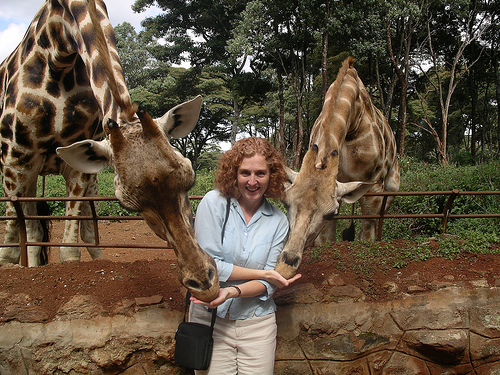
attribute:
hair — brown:
[212, 137, 289, 203]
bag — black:
[172, 286, 219, 373]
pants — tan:
[186, 299, 278, 374]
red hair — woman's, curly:
[218, 137, 285, 199]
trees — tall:
[105, 7, 205, 189]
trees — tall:
[189, 2, 282, 175]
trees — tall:
[290, 7, 382, 186]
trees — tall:
[377, 2, 451, 189]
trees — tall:
[423, 2, 495, 172]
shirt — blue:
[187, 187, 297, 298]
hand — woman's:
[263, 250, 303, 290]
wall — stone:
[0, 292, 491, 372]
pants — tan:
[178, 297, 278, 373]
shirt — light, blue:
[189, 196, 321, 309]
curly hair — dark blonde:
[221, 138, 288, 199]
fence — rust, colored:
[1, 188, 498, 265]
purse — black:
[164, 282, 211, 369]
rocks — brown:
[335, 299, 490, 352]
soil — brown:
[0, 235, 497, 323]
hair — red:
[215, 131, 291, 198]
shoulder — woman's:
[185, 183, 233, 220]